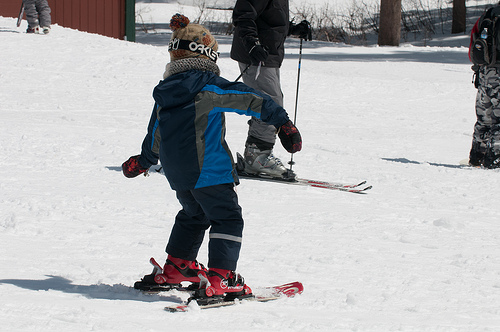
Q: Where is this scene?
A: Ski place.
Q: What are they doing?
A: Skiing.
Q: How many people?
A: 4.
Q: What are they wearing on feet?
A: Skis.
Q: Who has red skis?
A: The child.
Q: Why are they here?
A: To ski.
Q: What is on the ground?
A: Snow.